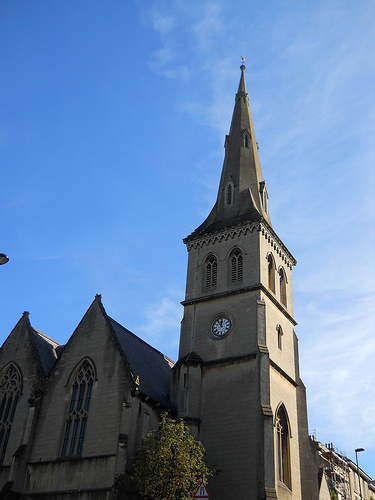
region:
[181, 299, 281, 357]
a clock on a building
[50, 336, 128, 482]
detailed windows on the side of a church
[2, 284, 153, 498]
attractive details in architecture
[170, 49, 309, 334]
a steeple on a building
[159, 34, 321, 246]
a steeple with a blue sky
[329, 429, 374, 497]
a street light beside a building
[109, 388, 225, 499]
a tree and sign in front of a building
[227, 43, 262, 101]
a weather vane on top of a building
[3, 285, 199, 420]
A high pitched roof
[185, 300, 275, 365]
Five minutes before twelve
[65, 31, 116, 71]
part of the sky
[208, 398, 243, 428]
wall of a building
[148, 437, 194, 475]
part of a tree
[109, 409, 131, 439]
edge of a building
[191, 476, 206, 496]
part of a post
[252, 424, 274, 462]
edge of a church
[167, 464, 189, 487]
part of a tree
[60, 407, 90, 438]
part of a window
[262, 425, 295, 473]
part of a window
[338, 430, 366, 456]
part of a lamp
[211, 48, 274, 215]
a very tall steeple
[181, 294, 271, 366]
a clock with a white face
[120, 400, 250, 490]
a half way dying tree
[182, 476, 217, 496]
red, black, and white sign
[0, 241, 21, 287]
part of a street light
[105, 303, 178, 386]
a shadow on the roof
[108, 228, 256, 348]
some clouds in the sky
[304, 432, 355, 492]
a scaffolding on the side of the building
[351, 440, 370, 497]
a full street light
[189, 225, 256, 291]
two windows that look the same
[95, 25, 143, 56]
part of the sky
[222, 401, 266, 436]
part of a wall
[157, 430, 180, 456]
part of a tree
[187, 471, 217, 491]
part of a road sign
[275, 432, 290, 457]
part of a window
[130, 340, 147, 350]
part of a roof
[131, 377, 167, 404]
edge of a roof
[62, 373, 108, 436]
part of a window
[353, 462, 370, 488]
part of a post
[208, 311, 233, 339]
a clock in the side of a building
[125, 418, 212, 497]
the tree next to the building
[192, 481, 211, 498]
the street sign next to the tree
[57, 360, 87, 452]
the fancy windows in the building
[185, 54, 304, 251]
the top of the tower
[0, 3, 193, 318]
the bright blue sky above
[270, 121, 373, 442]
a big cloud in the sky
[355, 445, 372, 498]
a street light next to the building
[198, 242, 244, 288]
some windows in the tower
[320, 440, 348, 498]
scaffolding in front of a building